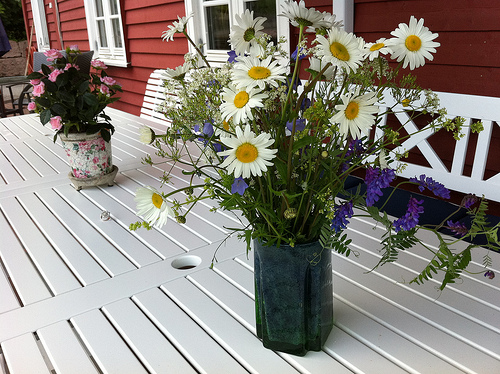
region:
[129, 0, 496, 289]
a bouquet of daisies and purple flowers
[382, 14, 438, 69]
a daisy has white petals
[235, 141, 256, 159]
the yellow center is a group of tiny flowers called the floral disc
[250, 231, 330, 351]
a blue green vase with a bouquet of flowers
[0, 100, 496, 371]
a white wood slat table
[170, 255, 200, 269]
the hole on the table is for an umbrella post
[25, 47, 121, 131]
a bouquet of pink roses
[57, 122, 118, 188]
a mosaic planter on a four legged stand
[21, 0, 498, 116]
a red paneled exterior wall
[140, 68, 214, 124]
a matching white slat bench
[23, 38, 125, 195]
Pot of pink roses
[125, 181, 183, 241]
A single daisy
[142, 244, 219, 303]
Hole in the white porch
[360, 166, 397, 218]
Purple flower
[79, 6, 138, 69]
Window in red house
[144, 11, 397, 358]
Pot of daisies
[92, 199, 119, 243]
A fallen flower bud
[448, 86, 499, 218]
White fence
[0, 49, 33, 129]
a table by the porch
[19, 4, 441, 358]
Two pots of flowers on the porch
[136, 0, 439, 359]
white daisies in vase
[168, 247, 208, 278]
hole in table for umbrella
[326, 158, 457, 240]
purple flowers under daisies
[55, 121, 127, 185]
flowers on white vase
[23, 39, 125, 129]
pink roses and leaves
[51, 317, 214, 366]
table made of white boards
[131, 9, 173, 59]
red exterior of house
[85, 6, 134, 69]
white wood around panes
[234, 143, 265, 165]
yellow center of daisy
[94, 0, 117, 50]
four panes on window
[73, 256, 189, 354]
white picket table top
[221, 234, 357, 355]
blue glass round vase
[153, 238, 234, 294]
hole for umbrella on top of table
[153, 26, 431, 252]
bunch of flowers in vase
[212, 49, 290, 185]
white daisies in bouquet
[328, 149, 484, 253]
purple flowers hanging off leaves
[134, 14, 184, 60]
red vinyl siding of house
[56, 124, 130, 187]
floral colored pot for flowers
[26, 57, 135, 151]
bouquet of pink roses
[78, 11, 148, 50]
white small paned window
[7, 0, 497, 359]
Exterior shot in daytime.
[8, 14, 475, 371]
Outdoor scene, suggesting summertime.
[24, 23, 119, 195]
Pink and white pottery vase with pink flowers and greenery.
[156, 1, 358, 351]
Tall, glass vase, featuring daisies and green stalks.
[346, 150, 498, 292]
Purple, cone-shaped blooms, hanging from vase.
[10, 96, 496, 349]
Long, white surface, probably table, holding vases.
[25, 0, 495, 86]
Exterior, red house with windows and gutter.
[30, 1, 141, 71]
White frame and gutter.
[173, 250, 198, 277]
Hole in table, suitable for positioning umbrella.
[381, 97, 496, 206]
Lattice-like detailing, resting near exterior of house.